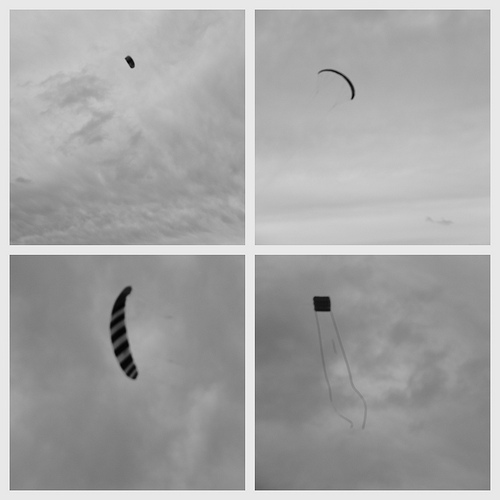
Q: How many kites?
A: 4.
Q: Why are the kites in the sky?
A: Flying them.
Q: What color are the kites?
A: Black and white.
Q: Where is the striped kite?
A: Bottom left.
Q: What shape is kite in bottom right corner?
A: Square.